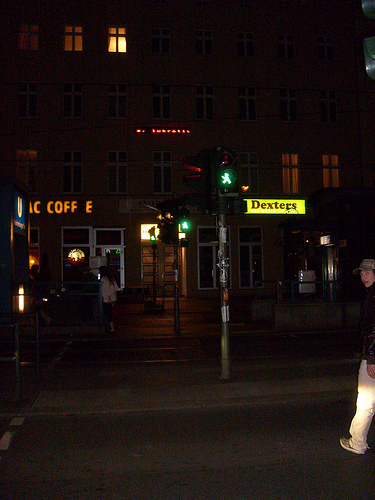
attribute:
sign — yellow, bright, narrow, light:
[240, 193, 312, 218]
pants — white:
[343, 358, 374, 453]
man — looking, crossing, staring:
[332, 257, 374, 457]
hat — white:
[353, 256, 371, 275]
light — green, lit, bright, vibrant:
[219, 167, 237, 188]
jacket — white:
[99, 274, 120, 303]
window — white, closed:
[236, 227, 267, 295]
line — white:
[0, 430, 17, 449]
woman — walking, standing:
[95, 265, 119, 332]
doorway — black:
[140, 239, 182, 297]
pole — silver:
[209, 203, 236, 385]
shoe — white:
[336, 434, 369, 455]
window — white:
[56, 223, 130, 295]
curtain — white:
[277, 149, 302, 197]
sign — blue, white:
[8, 190, 27, 236]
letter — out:
[76, 202, 85, 217]